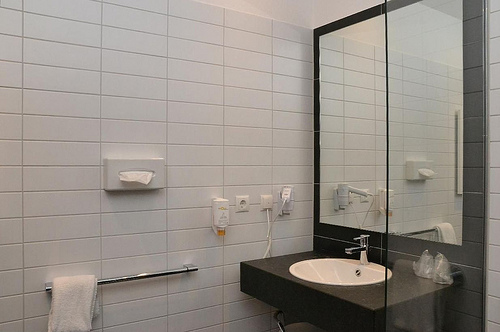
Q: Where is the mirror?
A: Above the sink.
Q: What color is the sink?
A: White.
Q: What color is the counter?
A: Black.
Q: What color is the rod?
A: Silver.